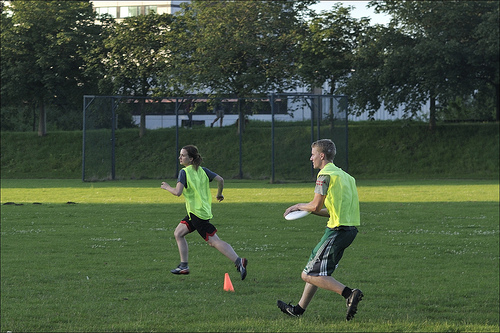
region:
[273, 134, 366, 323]
man on a field holding a frisbee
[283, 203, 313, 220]
white frisbee in a man's hand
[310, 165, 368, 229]
neon green top on a man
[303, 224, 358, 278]
black and green shorts on a man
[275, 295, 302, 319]
black shoe on a man's foot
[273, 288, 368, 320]
a black shoe on each of the man's feet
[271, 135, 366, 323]
man on a grassy field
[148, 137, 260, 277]
a young woman running on a grassy field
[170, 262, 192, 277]
shoe on a young woman's foot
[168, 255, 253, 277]
shoes on the young woman's feet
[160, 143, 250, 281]
Young woman playing Frisbee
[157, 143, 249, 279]
Young woman is running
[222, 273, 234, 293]
small orange boundary marker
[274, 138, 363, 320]
young man playing Frisbee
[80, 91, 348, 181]
goal is made of metal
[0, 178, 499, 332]
field is green grass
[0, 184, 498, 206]
grassy area is sunny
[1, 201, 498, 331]
grassy area is shady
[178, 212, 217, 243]
young woman wearing black shorts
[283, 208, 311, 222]
young man holding white Frisbee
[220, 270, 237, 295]
Orange traffic cone laying in the grass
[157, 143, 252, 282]
Girl in a green vest playing frisbee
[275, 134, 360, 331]
Young man in a green vest playing frisbee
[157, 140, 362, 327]
Couple of youngsters playing frisbee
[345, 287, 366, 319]
Cleats worn by frisbee player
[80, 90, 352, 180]
Chain-link fence in the background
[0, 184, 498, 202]
Ray of sunlight on the ground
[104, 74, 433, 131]
White building in the background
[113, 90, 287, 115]
Windows in a white building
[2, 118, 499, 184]
Hill surrounding the sports field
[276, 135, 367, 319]
young man playing frisbee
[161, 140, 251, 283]
young lady running on field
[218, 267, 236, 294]
a small orange cone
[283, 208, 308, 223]
a white round frisbee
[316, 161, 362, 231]
a yellow team vest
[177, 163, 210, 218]
a yellow team vest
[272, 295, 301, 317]
a black athletic shoe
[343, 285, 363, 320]
a black athletic shoe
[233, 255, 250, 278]
a black athletic shoe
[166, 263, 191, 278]
a black athletic shoe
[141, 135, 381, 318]
Peoples playing frisbee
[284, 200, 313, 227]
White color frisbee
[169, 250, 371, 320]
Two pair of shoes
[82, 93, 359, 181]
Blue color metal with fencing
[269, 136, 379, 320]
A man holding the frisbee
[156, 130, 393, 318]
A man running behind the woman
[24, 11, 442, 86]
Lot of trees near the metal fencing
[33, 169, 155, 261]
Green color grass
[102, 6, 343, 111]
Building near the tree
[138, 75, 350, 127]
White color building